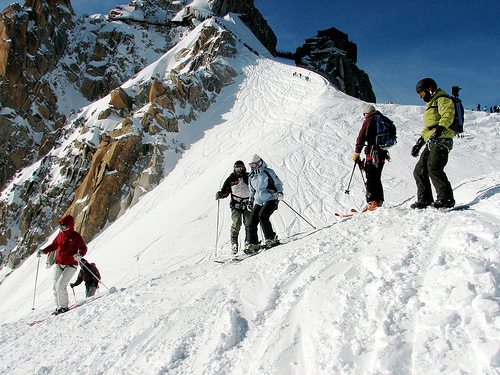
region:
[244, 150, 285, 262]
woman wearing blue ski jacket and black pants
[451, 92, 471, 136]
blue and black backpack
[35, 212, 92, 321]
woman wearing black ski jacket and white pants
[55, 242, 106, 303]
persn skiing in black behind woman in red jacket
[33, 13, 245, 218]
snow covered rocky mountain top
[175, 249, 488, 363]
snow on the ground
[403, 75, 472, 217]
skier in black pants and yellow ski jacket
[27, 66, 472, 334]
group of people skiing down a snowy hill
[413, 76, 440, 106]
man wearing black safety helmet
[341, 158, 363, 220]
black ski pole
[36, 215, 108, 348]
A woman skiing down a slope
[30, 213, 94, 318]
Woman wearing red jacket and trousers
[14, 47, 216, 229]
Rocks covered in snow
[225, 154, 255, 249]
A man wearing ski goggles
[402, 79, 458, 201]
A man wearing a green jacket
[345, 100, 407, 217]
A woman holding two ski poles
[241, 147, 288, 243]
Person wearing a light blue jacket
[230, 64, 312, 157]
Tracks from former skiers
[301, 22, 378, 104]
A rocky outcrop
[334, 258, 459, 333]
Snow covering the ground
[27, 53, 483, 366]
skiers on a slope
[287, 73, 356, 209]
ski marks in the snow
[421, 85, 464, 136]
man has a yellow jacktet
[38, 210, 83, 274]
woman has a red jacket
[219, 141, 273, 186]
people are wearing goggles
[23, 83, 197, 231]
snow missing on the mountain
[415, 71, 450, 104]
man is wearing a helmet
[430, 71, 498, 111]
people on top of the slope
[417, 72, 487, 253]
man is snowboarding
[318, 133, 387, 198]
person is holding his poles in his hand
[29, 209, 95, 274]
Person wearing a red parka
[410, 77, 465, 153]
man wearing yellow parka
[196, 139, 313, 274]
two people wearing goggles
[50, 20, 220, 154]
snow covered rocks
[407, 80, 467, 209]
man on snowboard on ski slope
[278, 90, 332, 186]
ski tracks in the snow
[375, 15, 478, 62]
bright blue sky in the background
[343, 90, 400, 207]
person on skis wearing blue backpack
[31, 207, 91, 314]
person skiing down the slope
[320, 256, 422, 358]
white snow powder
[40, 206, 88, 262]
Red jacket of first skier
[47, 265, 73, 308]
White pants worn by first skier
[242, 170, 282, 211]
Blue jacket worn by female skier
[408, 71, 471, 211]
Man standing on hillside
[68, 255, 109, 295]
Skier in the distance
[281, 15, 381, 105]
Big rock on montain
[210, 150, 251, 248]
Man wearing black and white ski outfit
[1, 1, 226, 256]
Snowy rocky mountainside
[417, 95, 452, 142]
Green jacket worn my male skier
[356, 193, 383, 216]
Red ski boots